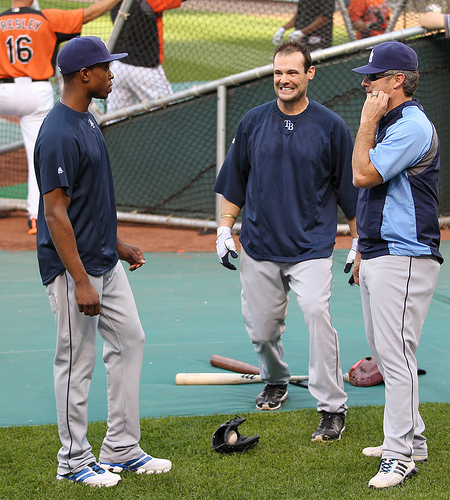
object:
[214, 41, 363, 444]
man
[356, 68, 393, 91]
sunglasses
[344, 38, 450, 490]
man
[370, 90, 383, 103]
ring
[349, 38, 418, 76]
cap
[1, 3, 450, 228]
netting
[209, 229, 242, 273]
gloves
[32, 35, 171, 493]
player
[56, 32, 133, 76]
hat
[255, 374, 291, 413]
foot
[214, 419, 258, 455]
mitt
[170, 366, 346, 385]
bat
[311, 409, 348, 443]
shoe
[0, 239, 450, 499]
ground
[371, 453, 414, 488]
shoes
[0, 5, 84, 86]
shirt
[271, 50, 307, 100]
face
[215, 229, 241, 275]
hand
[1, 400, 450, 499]
field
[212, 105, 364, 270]
shirt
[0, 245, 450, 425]
floor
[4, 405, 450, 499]
grass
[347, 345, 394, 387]
glove